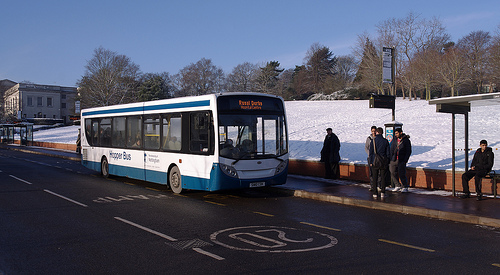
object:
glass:
[220, 114, 287, 159]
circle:
[211, 225, 340, 254]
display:
[238, 100, 264, 110]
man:
[461, 138, 493, 199]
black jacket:
[468, 147, 494, 173]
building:
[3, 81, 75, 131]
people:
[318, 128, 343, 180]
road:
[4, 149, 495, 273]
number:
[226, 228, 315, 249]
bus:
[80, 91, 290, 195]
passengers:
[366, 127, 392, 198]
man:
[387, 128, 412, 193]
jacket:
[387, 135, 412, 162]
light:
[274, 160, 288, 175]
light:
[222, 165, 237, 177]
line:
[44, 187, 88, 211]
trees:
[74, 45, 172, 106]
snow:
[287, 98, 357, 130]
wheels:
[166, 165, 179, 192]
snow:
[47, 124, 80, 144]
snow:
[478, 100, 498, 134]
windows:
[84, 109, 216, 156]